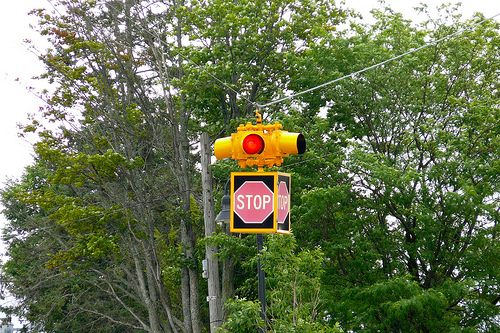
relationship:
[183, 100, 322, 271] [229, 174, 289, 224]
signal for a stop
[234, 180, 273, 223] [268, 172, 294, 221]
sign surrounded by border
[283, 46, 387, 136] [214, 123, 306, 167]
cable holding up signal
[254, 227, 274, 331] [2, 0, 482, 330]
post among trees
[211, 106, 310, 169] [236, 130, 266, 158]
framework holding light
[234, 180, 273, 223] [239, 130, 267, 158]
sign below light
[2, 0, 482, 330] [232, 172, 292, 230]
trees behind sign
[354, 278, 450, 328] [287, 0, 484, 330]
leaves on tree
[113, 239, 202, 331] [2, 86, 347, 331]
branches of trees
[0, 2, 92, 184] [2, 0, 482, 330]
sky behind trees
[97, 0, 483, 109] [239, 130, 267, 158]
rope holding light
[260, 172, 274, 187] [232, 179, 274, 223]
blackness behind sign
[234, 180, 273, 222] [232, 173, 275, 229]
sign with background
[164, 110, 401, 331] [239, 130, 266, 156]
tree behind light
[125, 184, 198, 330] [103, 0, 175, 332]
branches on green trees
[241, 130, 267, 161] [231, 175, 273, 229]
light above sign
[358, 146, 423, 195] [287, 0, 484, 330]
leaves on tree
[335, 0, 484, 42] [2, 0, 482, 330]
sky behind trees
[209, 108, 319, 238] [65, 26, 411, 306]
bracket connecting light